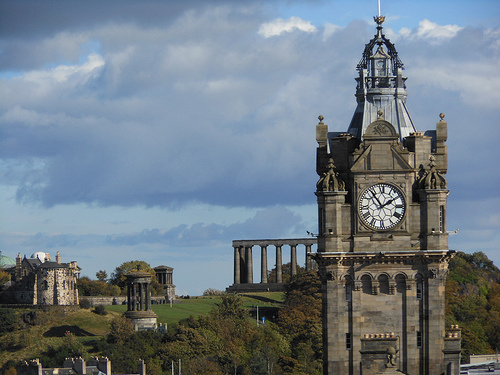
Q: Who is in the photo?
A: No one.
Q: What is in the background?
A: Columns.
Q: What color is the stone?
A: Grey.